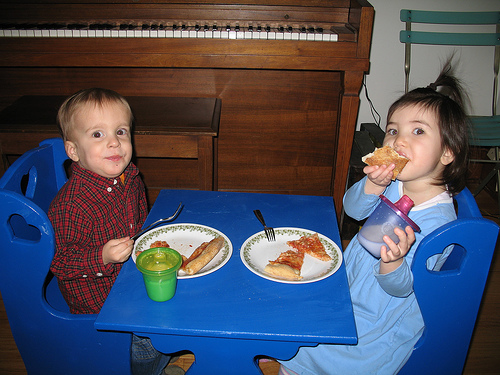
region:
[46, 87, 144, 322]
small boy eating lunch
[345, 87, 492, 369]
a little girl eating lunch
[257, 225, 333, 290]
2 slices of pizza on a white plate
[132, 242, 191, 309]
a green childs spillproof cup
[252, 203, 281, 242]
a fork on top of a plate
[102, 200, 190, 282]
a fork in a boys hand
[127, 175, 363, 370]
two white plates on top of a table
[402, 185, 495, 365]
a childs chair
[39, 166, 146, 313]
a boys red flannel shirt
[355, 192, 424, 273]
a blue sippy cup in a girls hand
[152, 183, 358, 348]
the table is blue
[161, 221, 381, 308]
there are two plates on the table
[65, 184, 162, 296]
the shirt is checked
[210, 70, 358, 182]
the piano is wooden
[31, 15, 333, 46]
the piano keys are white and black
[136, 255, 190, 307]
the cup is green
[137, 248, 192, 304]
the cup is half full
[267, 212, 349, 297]
two pieces of pizza on the plate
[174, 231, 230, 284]
there is hot dog on the plate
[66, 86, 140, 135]
his hair is brown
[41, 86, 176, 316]
a toddler boy wearing red plaid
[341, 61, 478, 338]
a toddler girl wearing blue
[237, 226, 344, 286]
two pieces of pizza on a white plate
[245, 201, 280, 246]
a metal fork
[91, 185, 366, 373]
a blue children's table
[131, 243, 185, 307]
green sippy cup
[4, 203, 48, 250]
a heart carved out of the chair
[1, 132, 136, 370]
blue children's chair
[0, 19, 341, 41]
black and white piano keys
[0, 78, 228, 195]
wooden piano bench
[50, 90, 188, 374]
Little boy in checkered shirt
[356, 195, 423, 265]
plastic sippy cup with red lid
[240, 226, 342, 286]
white plate with green decoration on it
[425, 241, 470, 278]
heart cut out on the blue seat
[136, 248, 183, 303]
green colored plastic cup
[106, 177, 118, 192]
two white buttons on boys shirt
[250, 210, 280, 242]
silver metal fork on plate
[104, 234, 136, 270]
boys right hand holding a fork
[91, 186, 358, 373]
bright blue colored table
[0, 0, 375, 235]
Large brown piano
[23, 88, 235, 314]
A toddler boy eating pizza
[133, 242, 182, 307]
A green sippy cup for toddlers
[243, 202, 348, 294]
A plate of pizza with a fork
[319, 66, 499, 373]
A toddler girl eating pizza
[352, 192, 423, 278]
A purple sippy cup for toddlers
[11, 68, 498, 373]
Two toddlers eating pizza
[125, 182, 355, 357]
A blue table containing plates of pizza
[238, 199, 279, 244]
A fork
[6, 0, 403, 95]
A piano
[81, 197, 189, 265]
A child holding a fork